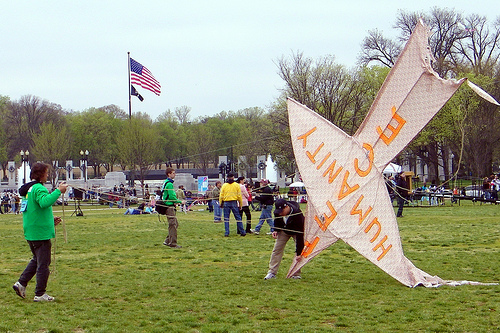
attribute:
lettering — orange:
[296, 109, 406, 261]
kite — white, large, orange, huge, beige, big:
[281, 21, 461, 285]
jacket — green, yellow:
[21, 186, 62, 240]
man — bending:
[266, 198, 307, 281]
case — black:
[154, 200, 168, 213]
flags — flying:
[127, 54, 162, 101]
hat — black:
[273, 200, 286, 215]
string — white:
[62, 138, 317, 236]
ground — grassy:
[0, 199, 499, 331]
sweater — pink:
[241, 182, 249, 209]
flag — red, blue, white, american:
[129, 60, 162, 94]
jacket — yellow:
[218, 182, 242, 203]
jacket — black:
[273, 209, 307, 248]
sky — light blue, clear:
[2, 1, 497, 115]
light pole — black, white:
[18, 148, 29, 184]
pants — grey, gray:
[26, 243, 52, 292]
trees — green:
[3, 102, 498, 162]